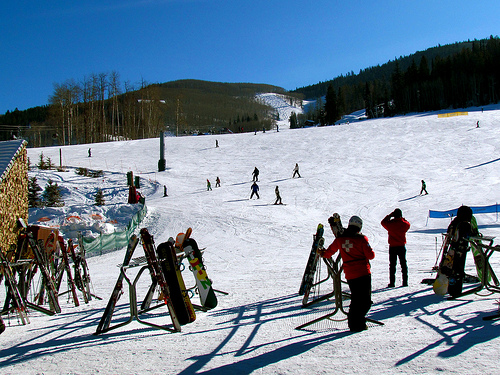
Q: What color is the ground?
A: White.